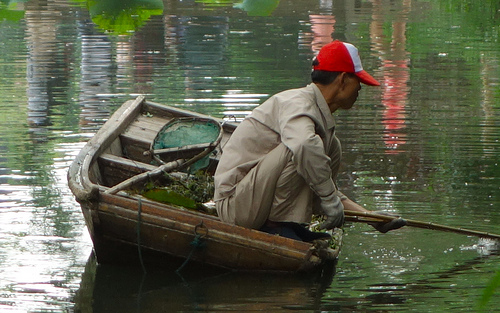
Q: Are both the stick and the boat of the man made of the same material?
A: Yes, both the stick and the boat are made of wood.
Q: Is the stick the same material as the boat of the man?
A: Yes, both the stick and the boat are made of wood.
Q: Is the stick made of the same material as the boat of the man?
A: Yes, both the stick and the boat are made of wood.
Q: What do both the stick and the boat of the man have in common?
A: The material, both the stick and the boat are wooden.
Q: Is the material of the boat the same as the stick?
A: Yes, both the boat and the stick are made of wood.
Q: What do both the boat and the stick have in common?
A: The material, both the boat and the stick are wooden.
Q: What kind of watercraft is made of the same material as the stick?
A: The boat is made of the same material as the stick.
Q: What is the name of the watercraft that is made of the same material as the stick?
A: The watercraft is a boat.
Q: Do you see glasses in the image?
A: No, there are no glasses.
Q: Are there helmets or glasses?
A: No, there are no glasses or helmets.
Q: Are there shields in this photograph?
A: No, there are no shields.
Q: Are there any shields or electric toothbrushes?
A: No, there are no shields or electric toothbrushes.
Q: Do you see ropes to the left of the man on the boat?
A: Yes, there is a rope to the left of the man.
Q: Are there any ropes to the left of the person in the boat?
A: Yes, there is a rope to the left of the man.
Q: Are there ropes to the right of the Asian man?
A: No, the rope is to the left of the man.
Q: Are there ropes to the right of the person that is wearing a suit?
A: No, the rope is to the left of the man.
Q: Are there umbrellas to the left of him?
A: No, there is a rope to the left of the man.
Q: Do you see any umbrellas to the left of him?
A: No, there is a rope to the left of the man.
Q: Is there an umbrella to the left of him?
A: No, there is a rope to the left of the man.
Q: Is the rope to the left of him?
A: Yes, the rope is to the left of the man.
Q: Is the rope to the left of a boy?
A: No, the rope is to the left of the man.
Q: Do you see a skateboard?
A: No, there are no skateboards.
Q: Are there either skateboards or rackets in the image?
A: No, there are no skateboards or rackets.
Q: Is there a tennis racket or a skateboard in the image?
A: No, there are no skateboards or rackets.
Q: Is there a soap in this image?
A: No, there are no soaps.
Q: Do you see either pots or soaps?
A: No, there are no soaps or pots.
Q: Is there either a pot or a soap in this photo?
A: No, there are no soaps or pots.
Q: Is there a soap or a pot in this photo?
A: No, there are no soaps or pots.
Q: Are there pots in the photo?
A: No, there are no pots.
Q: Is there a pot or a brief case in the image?
A: No, there are no pots or briefcases.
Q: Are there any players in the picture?
A: No, there are no players.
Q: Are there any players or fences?
A: No, there are no players or fences.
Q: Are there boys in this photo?
A: No, there are no boys.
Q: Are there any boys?
A: No, there are no boys.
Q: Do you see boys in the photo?
A: No, there are no boys.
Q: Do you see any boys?
A: No, there are no boys.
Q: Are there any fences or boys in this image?
A: No, there are no boys or fences.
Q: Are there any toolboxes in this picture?
A: No, there are no toolboxes.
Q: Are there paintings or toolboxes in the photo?
A: No, there are no toolboxes or paintings.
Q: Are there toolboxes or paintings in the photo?
A: No, there are no toolboxes or paintings.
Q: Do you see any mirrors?
A: No, there are no mirrors.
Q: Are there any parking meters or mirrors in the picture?
A: No, there are no mirrors or parking meters.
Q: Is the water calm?
A: Yes, the water is calm.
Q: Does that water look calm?
A: Yes, the water is calm.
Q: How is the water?
A: The water is calm.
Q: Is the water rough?
A: No, the water is calm.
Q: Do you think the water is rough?
A: No, the water is calm.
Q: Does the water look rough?
A: No, the water is calm.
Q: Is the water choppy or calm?
A: The water is calm.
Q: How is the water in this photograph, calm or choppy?
A: The water is calm.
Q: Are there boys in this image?
A: No, there are no boys.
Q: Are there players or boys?
A: No, there are no boys or players.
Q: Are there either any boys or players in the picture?
A: No, there are no boys or players.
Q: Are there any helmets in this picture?
A: No, there are no helmets.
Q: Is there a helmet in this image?
A: No, there are no helmets.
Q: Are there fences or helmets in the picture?
A: No, there are no helmets or fences.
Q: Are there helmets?
A: No, there are no helmets.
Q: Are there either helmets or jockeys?
A: No, there are no helmets or jockeys.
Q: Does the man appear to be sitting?
A: Yes, the man is sitting.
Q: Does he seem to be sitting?
A: Yes, the man is sitting.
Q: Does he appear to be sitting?
A: Yes, the man is sitting.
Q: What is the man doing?
A: The man is sitting.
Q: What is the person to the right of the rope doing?
A: The man is sitting.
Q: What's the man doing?
A: The man is sitting.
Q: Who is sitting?
A: The man is sitting.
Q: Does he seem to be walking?
A: No, the man is sitting.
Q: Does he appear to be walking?
A: No, the man is sitting.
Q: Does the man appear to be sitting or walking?
A: The man is sitting.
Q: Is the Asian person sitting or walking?
A: The man is sitting.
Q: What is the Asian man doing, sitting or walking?
A: The man is sitting.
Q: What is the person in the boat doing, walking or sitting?
A: The man is sitting.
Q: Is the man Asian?
A: Yes, the man is asian.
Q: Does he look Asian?
A: Yes, the man is asian.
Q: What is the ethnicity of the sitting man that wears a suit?
A: The man is asian.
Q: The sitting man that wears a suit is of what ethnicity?
A: The man is asian.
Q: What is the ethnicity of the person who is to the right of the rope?
A: The man is asian.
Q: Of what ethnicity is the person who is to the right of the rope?
A: The man is asian.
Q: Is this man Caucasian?
A: No, the man is asian.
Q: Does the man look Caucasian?
A: No, the man is asian.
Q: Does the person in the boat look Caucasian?
A: No, the man is asian.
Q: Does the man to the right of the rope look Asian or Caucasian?
A: The man is asian.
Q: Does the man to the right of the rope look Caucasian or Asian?
A: The man is asian.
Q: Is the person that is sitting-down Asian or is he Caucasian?
A: The man is asian.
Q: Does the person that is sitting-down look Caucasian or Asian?
A: The man is asian.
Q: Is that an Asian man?
A: Yes, that is an Asian man.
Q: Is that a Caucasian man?
A: No, that is an Asian man.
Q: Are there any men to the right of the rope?
A: Yes, there is a man to the right of the rope.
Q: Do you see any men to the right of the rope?
A: Yes, there is a man to the right of the rope.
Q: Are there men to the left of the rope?
A: No, the man is to the right of the rope.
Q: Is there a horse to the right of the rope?
A: No, there is a man to the right of the rope.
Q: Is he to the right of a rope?
A: Yes, the man is to the right of a rope.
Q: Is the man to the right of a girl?
A: No, the man is to the right of a rope.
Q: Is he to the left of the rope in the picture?
A: No, the man is to the right of the rope.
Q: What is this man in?
A: The man is in the boat.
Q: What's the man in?
A: The man is in the boat.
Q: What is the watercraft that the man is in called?
A: The watercraft is a boat.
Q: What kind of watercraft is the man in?
A: The man is in the boat.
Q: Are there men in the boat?
A: Yes, there is a man in the boat.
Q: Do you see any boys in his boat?
A: No, there is a man in the boat.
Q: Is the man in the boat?
A: Yes, the man is in the boat.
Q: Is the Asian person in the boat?
A: Yes, the man is in the boat.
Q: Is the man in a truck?
A: No, the man is in the boat.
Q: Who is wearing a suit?
A: The man is wearing a suit.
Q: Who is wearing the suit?
A: The man is wearing a suit.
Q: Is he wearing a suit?
A: Yes, the man is wearing a suit.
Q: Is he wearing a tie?
A: No, the man is wearing a suit.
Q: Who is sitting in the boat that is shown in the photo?
A: The man is sitting in the boat.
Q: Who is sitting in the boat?
A: The man is sitting in the boat.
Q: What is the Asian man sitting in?
A: The man is sitting in the boat.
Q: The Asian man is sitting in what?
A: The man is sitting in the boat.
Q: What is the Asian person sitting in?
A: The man is sitting in the boat.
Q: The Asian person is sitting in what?
A: The man is sitting in the boat.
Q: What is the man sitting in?
A: The man is sitting in the boat.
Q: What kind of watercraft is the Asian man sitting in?
A: The man is sitting in the boat.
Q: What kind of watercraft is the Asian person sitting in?
A: The man is sitting in the boat.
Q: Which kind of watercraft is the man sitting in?
A: The man is sitting in the boat.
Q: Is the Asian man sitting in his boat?
A: Yes, the man is sitting in the boat.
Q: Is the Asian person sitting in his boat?
A: Yes, the man is sitting in the boat.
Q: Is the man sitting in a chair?
A: No, the man is sitting in the boat.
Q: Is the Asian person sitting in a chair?
A: No, the man is sitting in the boat.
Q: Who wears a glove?
A: The man wears a glove.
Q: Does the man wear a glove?
A: Yes, the man wears a glove.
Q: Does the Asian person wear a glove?
A: Yes, the man wears a glove.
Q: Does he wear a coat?
A: No, the man wears a glove.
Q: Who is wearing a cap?
A: The man is wearing a cap.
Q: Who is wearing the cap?
A: The man is wearing a cap.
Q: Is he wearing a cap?
A: Yes, the man is wearing a cap.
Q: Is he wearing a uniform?
A: No, the man is wearing a cap.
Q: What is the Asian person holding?
A: The man is holding the net.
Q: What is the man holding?
A: The man is holding the net.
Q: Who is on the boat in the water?
A: The man is on the boat.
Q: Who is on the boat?
A: The man is on the boat.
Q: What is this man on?
A: The man is on the boat.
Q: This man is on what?
A: The man is on the boat.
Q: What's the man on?
A: The man is on the boat.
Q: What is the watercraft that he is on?
A: The watercraft is a boat.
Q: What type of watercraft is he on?
A: The man is on the boat.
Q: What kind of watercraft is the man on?
A: The man is on the boat.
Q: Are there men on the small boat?
A: Yes, there is a man on the boat.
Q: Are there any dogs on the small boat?
A: No, there is a man on the boat.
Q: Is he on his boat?
A: Yes, the man is on the boat.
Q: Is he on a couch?
A: No, the man is on the boat.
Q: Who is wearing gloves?
A: The man is wearing gloves.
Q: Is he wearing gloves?
A: Yes, the man is wearing gloves.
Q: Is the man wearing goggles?
A: No, the man is wearing gloves.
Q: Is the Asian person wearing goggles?
A: No, the man is wearing gloves.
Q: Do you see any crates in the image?
A: No, there are no crates.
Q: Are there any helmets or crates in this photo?
A: No, there are no crates or helmets.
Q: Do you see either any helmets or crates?
A: No, there are no crates or helmets.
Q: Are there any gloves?
A: Yes, there are gloves.